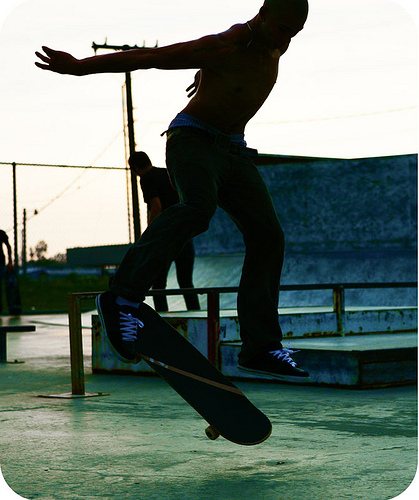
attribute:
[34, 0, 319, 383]
person — skateboarding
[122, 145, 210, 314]
person — skateboarding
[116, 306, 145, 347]
shoelaces — white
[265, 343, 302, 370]
shoelaces — white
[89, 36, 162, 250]
electrical pole — wooden, tall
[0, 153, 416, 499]
skateboard park — concrete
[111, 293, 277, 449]
skateboard — black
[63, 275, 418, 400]
railing — metal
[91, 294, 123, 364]
soles — white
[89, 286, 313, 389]
sneakers — black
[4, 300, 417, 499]
ground — cement